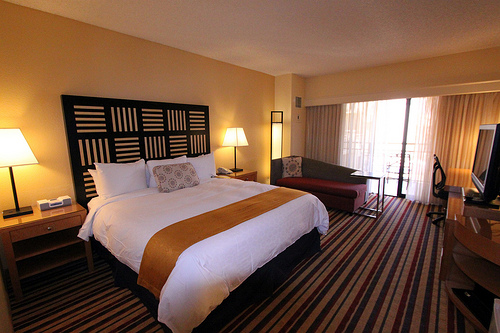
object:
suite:
[56, 86, 334, 315]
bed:
[78, 149, 331, 332]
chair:
[270, 173, 368, 214]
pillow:
[280, 155, 305, 180]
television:
[461, 121, 500, 207]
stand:
[442, 220, 499, 315]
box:
[37, 194, 75, 212]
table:
[0, 200, 99, 290]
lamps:
[0, 127, 40, 221]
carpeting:
[250, 193, 448, 301]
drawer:
[0, 212, 87, 248]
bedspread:
[94, 178, 332, 332]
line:
[158, 187, 237, 215]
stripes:
[44, 287, 123, 313]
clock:
[215, 165, 235, 178]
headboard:
[58, 91, 212, 206]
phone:
[215, 161, 235, 175]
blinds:
[303, 97, 426, 196]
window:
[340, 96, 430, 204]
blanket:
[136, 185, 309, 299]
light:
[0, 127, 41, 171]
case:
[150, 161, 201, 193]